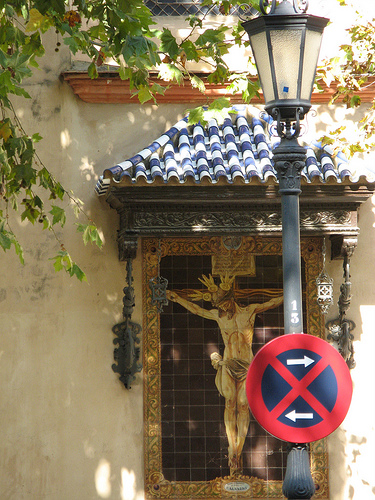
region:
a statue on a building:
[181, 277, 253, 465]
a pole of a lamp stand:
[275, 191, 316, 331]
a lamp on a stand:
[249, 9, 320, 115]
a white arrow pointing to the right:
[287, 354, 312, 370]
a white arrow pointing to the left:
[284, 409, 315, 421]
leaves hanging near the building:
[27, 0, 203, 72]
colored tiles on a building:
[151, 124, 259, 177]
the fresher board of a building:
[65, 71, 233, 104]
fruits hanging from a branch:
[55, 26, 60, 53]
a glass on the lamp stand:
[272, 34, 299, 74]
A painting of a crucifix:
[116, 220, 331, 498]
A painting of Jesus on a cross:
[131, 233, 330, 497]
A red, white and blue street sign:
[235, 304, 360, 476]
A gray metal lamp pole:
[259, 126, 328, 332]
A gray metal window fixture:
[105, 228, 147, 395]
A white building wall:
[15, 279, 108, 483]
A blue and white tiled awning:
[78, 95, 373, 203]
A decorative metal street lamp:
[223, 3, 347, 199]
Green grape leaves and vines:
[47, 7, 255, 108]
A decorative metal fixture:
[312, 237, 339, 317]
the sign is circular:
[263, 338, 349, 429]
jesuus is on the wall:
[161, 292, 286, 473]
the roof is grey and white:
[163, 136, 269, 163]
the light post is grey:
[283, 234, 300, 294]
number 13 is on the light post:
[287, 298, 305, 330]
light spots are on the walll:
[91, 455, 140, 497]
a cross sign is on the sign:
[247, 339, 347, 431]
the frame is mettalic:
[178, 217, 258, 235]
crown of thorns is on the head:
[209, 281, 240, 301]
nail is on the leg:
[222, 449, 251, 467]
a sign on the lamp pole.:
[219, 332, 343, 427]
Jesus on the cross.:
[177, 261, 270, 393]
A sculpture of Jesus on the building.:
[163, 258, 286, 379]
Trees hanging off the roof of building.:
[39, 5, 231, 101]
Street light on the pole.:
[240, 9, 337, 124]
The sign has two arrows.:
[250, 339, 346, 444]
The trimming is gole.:
[137, 244, 168, 459]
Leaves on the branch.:
[102, 23, 228, 94]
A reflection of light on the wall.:
[85, 407, 141, 493]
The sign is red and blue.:
[258, 334, 333, 419]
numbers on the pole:
[286, 299, 301, 327]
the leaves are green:
[10, 176, 63, 229]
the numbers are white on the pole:
[289, 298, 299, 325]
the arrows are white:
[279, 400, 304, 417]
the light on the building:
[90, 456, 140, 497]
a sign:
[250, 334, 351, 442]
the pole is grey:
[280, 210, 304, 293]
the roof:
[164, 167, 239, 179]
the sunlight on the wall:
[90, 463, 135, 498]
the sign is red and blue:
[245, 335, 356, 440]